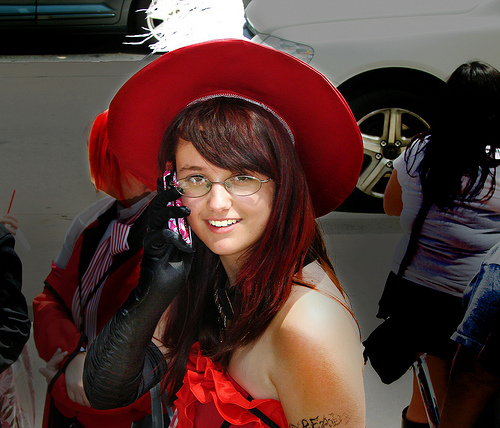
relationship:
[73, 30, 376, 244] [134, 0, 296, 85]
hat has feathers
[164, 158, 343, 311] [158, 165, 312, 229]
girl wearing eyeglasses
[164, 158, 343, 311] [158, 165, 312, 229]
girl earing eyeglasses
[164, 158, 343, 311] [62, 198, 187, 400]
girl wearing glove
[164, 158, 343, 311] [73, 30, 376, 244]
girl wearing hat